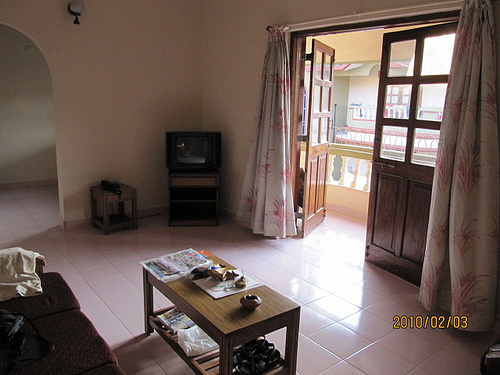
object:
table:
[141, 246, 302, 374]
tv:
[165, 131, 221, 173]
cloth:
[1, 246, 45, 301]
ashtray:
[240, 293, 260, 311]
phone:
[100, 179, 122, 200]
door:
[302, 36, 336, 236]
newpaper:
[157, 306, 193, 335]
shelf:
[133, 243, 301, 372]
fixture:
[65, 0, 83, 24]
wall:
[1, 1, 213, 226]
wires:
[1, 308, 56, 366]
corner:
[178, 1, 231, 209]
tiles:
[82, 241, 140, 308]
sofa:
[1, 248, 123, 375]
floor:
[1, 210, 490, 373]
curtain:
[234, 22, 299, 239]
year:
[391, 314, 424, 331]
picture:
[2, 2, 500, 375]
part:
[102, 49, 187, 92]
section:
[1, 307, 119, 374]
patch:
[416, 10, 477, 309]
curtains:
[417, 0, 500, 332]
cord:
[137, 206, 171, 219]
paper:
[139, 247, 213, 283]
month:
[430, 315, 447, 332]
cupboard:
[168, 174, 218, 226]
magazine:
[191, 267, 268, 298]